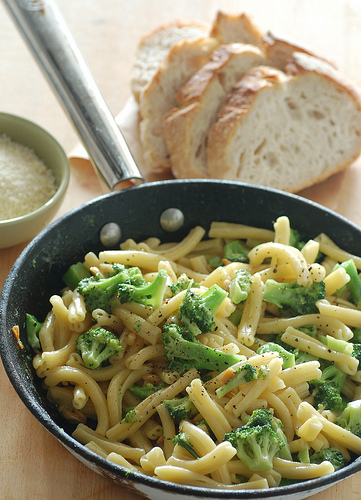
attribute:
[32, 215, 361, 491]
macaroni — yellow, cooked, cream colored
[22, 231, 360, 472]
broccoli — green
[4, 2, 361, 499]
pan — black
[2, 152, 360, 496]
counter — wood, brown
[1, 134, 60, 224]
rice — white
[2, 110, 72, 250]
bowl — white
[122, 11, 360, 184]
bread — sliced, brown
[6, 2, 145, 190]
handle — silver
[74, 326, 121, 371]
broccoli piece — green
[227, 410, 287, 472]
broccoli piece — green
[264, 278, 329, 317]
broccoli piece — green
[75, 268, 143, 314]
broccoli piece — green